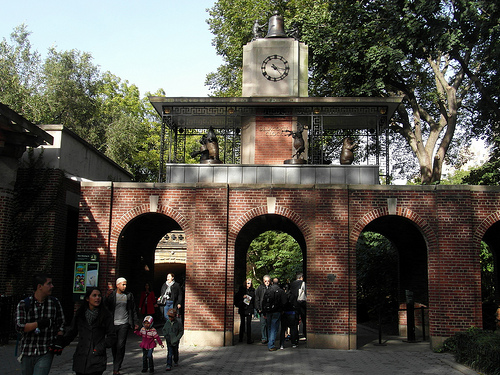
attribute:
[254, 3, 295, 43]
bell — metal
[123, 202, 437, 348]
archways — brick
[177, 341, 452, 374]
path — stone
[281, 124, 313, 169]
statue — animal, bronze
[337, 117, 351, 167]
statue — animal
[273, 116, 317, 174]
horse — bronze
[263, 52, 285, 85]
clock — black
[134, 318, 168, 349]
coat — pink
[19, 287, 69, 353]
shirt — plaid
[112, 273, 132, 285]
hat — white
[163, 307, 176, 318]
cap — orange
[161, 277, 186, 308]
cardigan — black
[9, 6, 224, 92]
sky — blue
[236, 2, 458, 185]
tree — green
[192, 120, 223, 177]
deer — statue